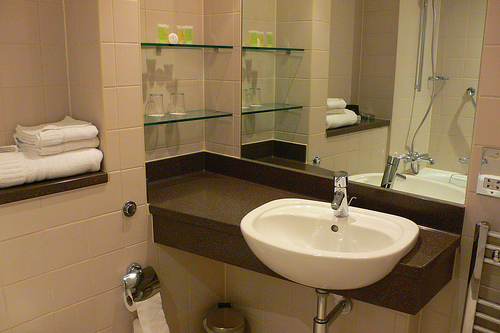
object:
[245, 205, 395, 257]
sink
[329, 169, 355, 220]
faucet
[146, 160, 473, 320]
counter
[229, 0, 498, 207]
mirror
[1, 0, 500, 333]
bathroom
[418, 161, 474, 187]
bathtub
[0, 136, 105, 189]
towel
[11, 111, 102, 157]
towel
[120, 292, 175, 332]
toilet paper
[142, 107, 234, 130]
shelf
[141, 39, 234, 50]
shelf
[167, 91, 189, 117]
glass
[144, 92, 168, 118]
glass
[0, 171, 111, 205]
shelf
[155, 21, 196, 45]
toiletries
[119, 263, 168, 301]
roll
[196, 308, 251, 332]
garbage can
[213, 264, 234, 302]
corner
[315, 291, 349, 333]
pipes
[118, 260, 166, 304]
toilet paper holder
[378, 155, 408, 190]
reflection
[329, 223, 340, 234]
drain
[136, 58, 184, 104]
shadow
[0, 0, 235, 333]
wall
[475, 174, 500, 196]
plug in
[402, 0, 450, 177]
shower